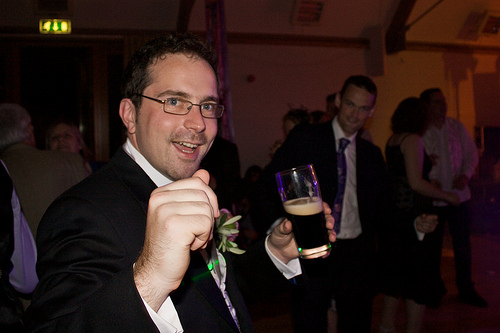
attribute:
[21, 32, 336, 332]
man — brunette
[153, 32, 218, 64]
hair — short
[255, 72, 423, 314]
man — smiling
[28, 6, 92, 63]
sign — green and yellow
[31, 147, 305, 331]
jacket — black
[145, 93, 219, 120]
eyeglasses — pair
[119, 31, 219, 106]
hair — brunette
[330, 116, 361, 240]
shirt — white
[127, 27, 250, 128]
hair — brown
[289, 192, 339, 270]
liquid — brown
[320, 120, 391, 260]
shirt — white